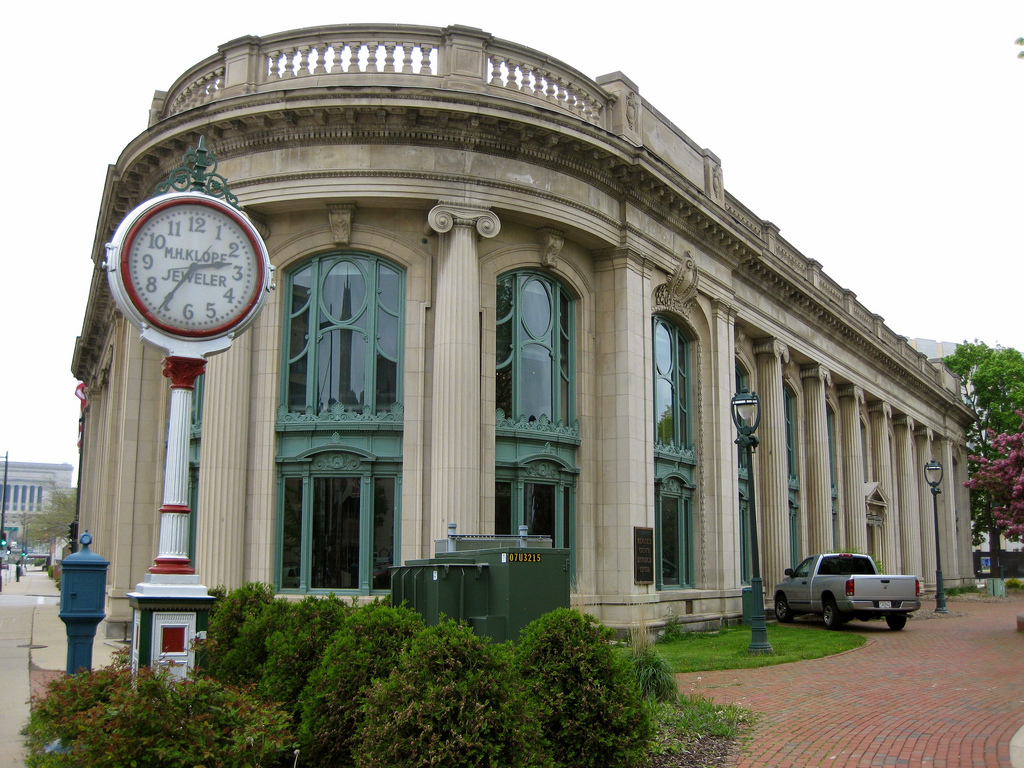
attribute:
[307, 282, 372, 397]
frame —  greenmetal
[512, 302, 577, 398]
frame —  greenmetal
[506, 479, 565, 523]
frame —  greenmetal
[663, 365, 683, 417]
frame —  greenmetal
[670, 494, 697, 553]
frame —  greenmetal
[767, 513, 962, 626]
truck —  grey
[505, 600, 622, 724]
bush — short and green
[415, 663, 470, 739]
bush — short and green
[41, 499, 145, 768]
post — bright blue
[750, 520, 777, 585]
pole — green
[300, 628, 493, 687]
shrubs — green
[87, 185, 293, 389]
clock — red and white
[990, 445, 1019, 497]
flowers — pink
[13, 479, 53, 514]
pillars — white and marble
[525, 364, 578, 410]
frame — green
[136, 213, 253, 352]
clock —  red and white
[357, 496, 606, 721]
box — green and metal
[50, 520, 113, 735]
pole — blue and metal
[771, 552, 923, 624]
truck — silver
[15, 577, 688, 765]
shrubs — green